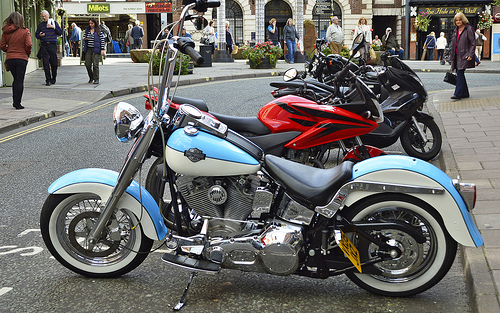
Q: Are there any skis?
A: No, there are no skis.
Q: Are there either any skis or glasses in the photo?
A: No, there are no skis or glasses.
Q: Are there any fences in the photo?
A: No, there are no fences.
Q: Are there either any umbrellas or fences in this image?
A: No, there are no fences or umbrellas.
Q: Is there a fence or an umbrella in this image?
A: No, there are no fences or umbrellas.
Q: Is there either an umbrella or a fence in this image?
A: No, there are no fences or umbrellas.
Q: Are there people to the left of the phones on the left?
A: Yes, there are people to the left of the phones.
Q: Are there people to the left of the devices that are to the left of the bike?
A: Yes, there are people to the left of the phones.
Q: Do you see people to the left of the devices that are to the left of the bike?
A: Yes, there are people to the left of the phones.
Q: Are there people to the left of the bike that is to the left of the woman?
A: Yes, there are people to the left of the bike.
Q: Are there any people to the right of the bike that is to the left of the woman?
A: No, the people are to the left of the bike.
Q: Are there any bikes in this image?
A: Yes, there is a bike.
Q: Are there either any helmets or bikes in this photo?
A: Yes, there is a bike.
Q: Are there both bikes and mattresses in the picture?
A: No, there is a bike but no mattresses.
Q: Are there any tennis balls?
A: No, there are no tennis balls.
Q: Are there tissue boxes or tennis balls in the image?
A: No, there are no tennis balls or tissue boxes.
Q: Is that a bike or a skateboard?
A: That is a bike.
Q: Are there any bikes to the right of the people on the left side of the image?
A: Yes, there is a bike to the right of the people.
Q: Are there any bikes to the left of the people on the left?
A: No, the bike is to the right of the people.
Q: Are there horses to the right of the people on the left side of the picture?
A: No, there is a bike to the right of the people.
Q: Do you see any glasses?
A: No, there are no glasses.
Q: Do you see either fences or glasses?
A: No, there are no glasses or fences.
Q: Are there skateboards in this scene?
A: No, there are no skateboards.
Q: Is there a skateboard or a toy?
A: No, there are no skateboards or toys.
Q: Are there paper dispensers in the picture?
A: No, there are no paper dispensers.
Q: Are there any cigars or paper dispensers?
A: No, there are no paper dispensers or cigars.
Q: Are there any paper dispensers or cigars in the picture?
A: No, there are no paper dispensers or cigars.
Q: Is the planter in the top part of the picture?
A: Yes, the planter is in the top of the image.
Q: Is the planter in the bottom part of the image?
A: No, the planter is in the top of the image.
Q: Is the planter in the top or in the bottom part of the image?
A: The planter is in the top of the image.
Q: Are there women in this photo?
A: Yes, there is a woman.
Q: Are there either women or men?
A: Yes, there is a woman.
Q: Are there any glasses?
A: No, there are no glasses.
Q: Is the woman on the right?
A: Yes, the woman is on the right of the image.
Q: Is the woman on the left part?
A: No, the woman is on the right of the image.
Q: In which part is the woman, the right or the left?
A: The woman is on the right of the image.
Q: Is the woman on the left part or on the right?
A: The woman is on the right of the image.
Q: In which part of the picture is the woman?
A: The woman is on the right of the image.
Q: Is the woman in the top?
A: Yes, the woman is in the top of the image.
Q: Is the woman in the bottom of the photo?
A: No, the woman is in the top of the image.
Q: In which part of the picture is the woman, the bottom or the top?
A: The woman is in the top of the image.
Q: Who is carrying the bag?
A: The woman is carrying the bag.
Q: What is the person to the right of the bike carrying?
A: The woman is carrying a bag.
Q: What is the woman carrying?
A: The woman is carrying a bag.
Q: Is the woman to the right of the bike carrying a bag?
A: Yes, the woman is carrying a bag.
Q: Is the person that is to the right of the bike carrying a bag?
A: Yes, the woman is carrying a bag.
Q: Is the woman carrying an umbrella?
A: No, the woman is carrying a bag.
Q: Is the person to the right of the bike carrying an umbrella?
A: No, the woman is carrying a bag.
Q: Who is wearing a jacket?
A: The woman is wearing a jacket.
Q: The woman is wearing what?
A: The woman is wearing a jacket.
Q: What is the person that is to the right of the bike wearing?
A: The woman is wearing a jacket.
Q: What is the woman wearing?
A: The woman is wearing a jacket.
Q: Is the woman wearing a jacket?
A: Yes, the woman is wearing a jacket.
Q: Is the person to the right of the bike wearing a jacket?
A: Yes, the woman is wearing a jacket.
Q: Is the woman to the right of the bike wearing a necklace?
A: No, the woman is wearing a jacket.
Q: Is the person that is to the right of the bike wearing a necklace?
A: No, the woman is wearing a jacket.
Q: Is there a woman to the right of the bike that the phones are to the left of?
A: Yes, there is a woman to the right of the bike.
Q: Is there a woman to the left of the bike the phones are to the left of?
A: No, the woman is to the right of the bike.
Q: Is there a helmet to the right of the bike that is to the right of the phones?
A: No, there is a woman to the right of the bike.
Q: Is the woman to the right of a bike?
A: Yes, the woman is to the right of a bike.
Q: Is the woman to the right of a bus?
A: No, the woman is to the right of a bike.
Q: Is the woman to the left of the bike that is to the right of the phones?
A: No, the woman is to the right of the bike.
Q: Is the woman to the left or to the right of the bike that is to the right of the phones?
A: The woman is to the right of the bike.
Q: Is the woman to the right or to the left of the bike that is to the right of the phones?
A: The woman is to the right of the bike.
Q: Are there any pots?
A: Yes, there is a pot.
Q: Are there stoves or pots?
A: Yes, there is a pot.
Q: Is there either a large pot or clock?
A: Yes, there is a large pot.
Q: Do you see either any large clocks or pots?
A: Yes, there is a large pot.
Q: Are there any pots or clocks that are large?
A: Yes, the pot is large.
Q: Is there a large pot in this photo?
A: Yes, there is a large pot.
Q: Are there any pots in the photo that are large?
A: Yes, there is a pot that is large.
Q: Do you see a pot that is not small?
A: Yes, there is a large pot.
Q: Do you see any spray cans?
A: No, there are no spray cans.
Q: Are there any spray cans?
A: No, there are no spray cans.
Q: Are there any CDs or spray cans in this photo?
A: No, there are no spray cans or cds.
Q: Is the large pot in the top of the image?
A: Yes, the pot is in the top of the image.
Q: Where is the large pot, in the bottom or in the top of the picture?
A: The pot is in the top of the image.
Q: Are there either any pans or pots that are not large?
A: No, there is a pot but it is large.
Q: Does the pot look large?
A: Yes, the pot is large.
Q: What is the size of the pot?
A: The pot is large.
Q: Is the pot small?
A: No, the pot is large.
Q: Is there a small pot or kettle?
A: No, there is a pot but it is large.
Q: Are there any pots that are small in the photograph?
A: No, there is a pot but it is large.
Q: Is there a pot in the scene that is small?
A: No, there is a pot but it is large.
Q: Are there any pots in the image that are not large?
A: No, there is a pot but it is large.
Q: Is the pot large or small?
A: The pot is large.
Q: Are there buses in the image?
A: No, there are no buses.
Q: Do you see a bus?
A: No, there are no buses.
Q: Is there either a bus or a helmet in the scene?
A: No, there are no buses or helmets.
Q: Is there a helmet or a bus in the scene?
A: No, there are no buses or helmets.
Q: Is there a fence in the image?
A: No, there are no fences.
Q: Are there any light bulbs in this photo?
A: No, there are no light bulbs.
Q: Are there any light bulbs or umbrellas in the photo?
A: No, there are no light bulbs or umbrellas.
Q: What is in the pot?
A: The flowers are in the pot.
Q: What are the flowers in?
A: The flowers are in the pot.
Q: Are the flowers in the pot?
A: Yes, the flowers are in the pot.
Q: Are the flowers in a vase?
A: No, the flowers are in the pot.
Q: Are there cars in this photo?
A: No, there are no cars.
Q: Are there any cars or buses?
A: No, there are no cars or buses.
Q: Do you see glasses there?
A: No, there are no glasses.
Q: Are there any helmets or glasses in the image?
A: No, there are no glasses or helmets.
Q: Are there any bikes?
A: Yes, there is a bike.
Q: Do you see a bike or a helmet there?
A: Yes, there is a bike.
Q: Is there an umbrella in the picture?
A: No, there are no umbrellas.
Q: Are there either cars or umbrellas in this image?
A: No, there are no umbrellas or cars.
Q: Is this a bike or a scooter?
A: This is a bike.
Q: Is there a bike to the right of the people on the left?
A: Yes, there is a bike to the right of the people.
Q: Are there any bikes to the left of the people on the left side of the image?
A: No, the bike is to the right of the people.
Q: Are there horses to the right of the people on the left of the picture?
A: No, there is a bike to the right of the people.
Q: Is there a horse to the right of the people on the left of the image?
A: No, there is a bike to the right of the people.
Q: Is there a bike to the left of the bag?
A: Yes, there is a bike to the left of the bag.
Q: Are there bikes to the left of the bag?
A: Yes, there is a bike to the left of the bag.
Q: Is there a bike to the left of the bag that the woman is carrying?
A: Yes, there is a bike to the left of the bag.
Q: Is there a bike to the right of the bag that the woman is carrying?
A: No, the bike is to the left of the bag.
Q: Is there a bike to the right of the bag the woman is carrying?
A: No, the bike is to the left of the bag.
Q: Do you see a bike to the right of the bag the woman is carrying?
A: No, the bike is to the left of the bag.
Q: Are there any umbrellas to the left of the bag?
A: No, there is a bike to the left of the bag.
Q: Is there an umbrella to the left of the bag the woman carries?
A: No, there is a bike to the left of the bag.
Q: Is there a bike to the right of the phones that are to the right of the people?
A: Yes, there is a bike to the right of the phones.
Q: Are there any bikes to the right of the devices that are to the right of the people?
A: Yes, there is a bike to the right of the phones.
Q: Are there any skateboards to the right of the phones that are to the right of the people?
A: No, there is a bike to the right of the phones.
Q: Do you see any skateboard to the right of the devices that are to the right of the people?
A: No, there is a bike to the right of the phones.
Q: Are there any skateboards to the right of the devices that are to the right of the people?
A: No, there is a bike to the right of the phones.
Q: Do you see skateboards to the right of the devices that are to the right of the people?
A: No, there is a bike to the right of the phones.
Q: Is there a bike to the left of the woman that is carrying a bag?
A: Yes, there is a bike to the left of the woman.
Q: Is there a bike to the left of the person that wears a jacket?
A: Yes, there is a bike to the left of the woman.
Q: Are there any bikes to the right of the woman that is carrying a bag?
A: No, the bike is to the left of the woman.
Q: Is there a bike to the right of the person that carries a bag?
A: No, the bike is to the left of the woman.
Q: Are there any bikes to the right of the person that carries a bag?
A: No, the bike is to the left of the woman.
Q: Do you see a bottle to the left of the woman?
A: No, there is a bike to the left of the woman.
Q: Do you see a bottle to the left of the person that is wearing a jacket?
A: No, there is a bike to the left of the woman.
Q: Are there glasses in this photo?
A: No, there are no glasses.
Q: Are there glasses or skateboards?
A: No, there are no glasses or skateboards.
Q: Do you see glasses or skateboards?
A: No, there are no glasses or skateboards.